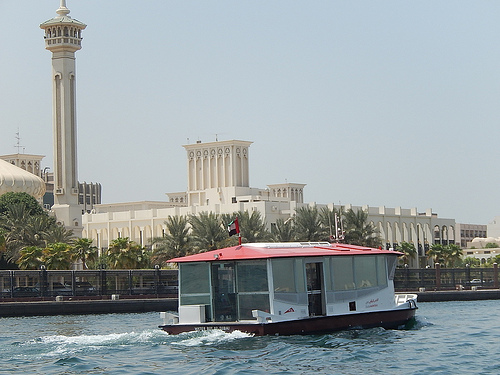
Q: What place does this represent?
A: It represents the city.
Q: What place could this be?
A: It is a city.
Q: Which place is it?
A: It is a city.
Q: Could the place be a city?
A: Yes, it is a city.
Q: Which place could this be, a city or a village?
A: It is a city.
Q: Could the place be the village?
A: No, it is the city.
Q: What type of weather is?
A: It is clear.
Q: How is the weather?
A: It is clear.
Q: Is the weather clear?
A: Yes, it is clear.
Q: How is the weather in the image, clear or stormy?
A: It is clear.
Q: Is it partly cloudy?
A: No, it is clear.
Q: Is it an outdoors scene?
A: Yes, it is outdoors.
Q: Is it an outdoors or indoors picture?
A: It is outdoors.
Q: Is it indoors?
A: No, it is outdoors.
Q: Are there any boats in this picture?
A: Yes, there is a boat.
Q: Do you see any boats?
A: Yes, there is a boat.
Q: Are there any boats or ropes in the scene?
A: Yes, there is a boat.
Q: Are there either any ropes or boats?
A: Yes, there is a boat.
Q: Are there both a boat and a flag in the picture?
A: Yes, there are both a boat and a flag.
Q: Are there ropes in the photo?
A: No, there are no ropes.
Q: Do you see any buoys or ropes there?
A: No, there are no ropes or buoys.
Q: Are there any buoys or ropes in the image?
A: No, there are no ropes or buoys.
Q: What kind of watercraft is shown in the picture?
A: The watercraft is a boat.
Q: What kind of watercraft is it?
A: The watercraft is a boat.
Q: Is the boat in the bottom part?
A: Yes, the boat is in the bottom of the image.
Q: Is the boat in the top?
A: No, the boat is in the bottom of the image.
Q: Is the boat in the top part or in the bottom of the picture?
A: The boat is in the bottom of the image.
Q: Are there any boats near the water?
A: Yes, there is a boat near the water.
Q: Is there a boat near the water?
A: Yes, there is a boat near the water.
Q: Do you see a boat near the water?
A: Yes, there is a boat near the water.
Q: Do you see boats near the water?
A: Yes, there is a boat near the water.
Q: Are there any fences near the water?
A: No, there is a boat near the water.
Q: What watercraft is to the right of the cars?
A: The watercraft is a boat.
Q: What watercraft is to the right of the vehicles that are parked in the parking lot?
A: The watercraft is a boat.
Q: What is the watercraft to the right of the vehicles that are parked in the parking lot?
A: The watercraft is a boat.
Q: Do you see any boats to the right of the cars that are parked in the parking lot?
A: Yes, there is a boat to the right of the cars.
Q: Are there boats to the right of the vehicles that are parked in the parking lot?
A: Yes, there is a boat to the right of the cars.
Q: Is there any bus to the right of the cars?
A: No, there is a boat to the right of the cars.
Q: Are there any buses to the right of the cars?
A: No, there is a boat to the right of the cars.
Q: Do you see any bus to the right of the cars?
A: No, there is a boat to the right of the cars.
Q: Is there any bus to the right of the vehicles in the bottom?
A: No, there is a boat to the right of the cars.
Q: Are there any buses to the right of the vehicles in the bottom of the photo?
A: No, there is a boat to the right of the cars.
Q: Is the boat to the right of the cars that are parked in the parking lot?
A: Yes, the boat is to the right of the cars.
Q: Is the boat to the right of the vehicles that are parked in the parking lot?
A: Yes, the boat is to the right of the cars.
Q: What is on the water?
A: The boat is on the water.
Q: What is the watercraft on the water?
A: The watercraft is a boat.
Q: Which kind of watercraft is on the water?
A: The watercraft is a boat.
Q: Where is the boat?
A: The boat is on the water.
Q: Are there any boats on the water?
A: Yes, there is a boat on the water.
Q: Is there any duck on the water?
A: No, there is a boat on the water.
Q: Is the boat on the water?
A: Yes, the boat is on the water.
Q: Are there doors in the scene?
A: Yes, there is a door.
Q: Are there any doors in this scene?
A: Yes, there is a door.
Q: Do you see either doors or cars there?
A: Yes, there is a door.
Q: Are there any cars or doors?
A: Yes, there is a door.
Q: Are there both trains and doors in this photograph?
A: No, there is a door but no trains.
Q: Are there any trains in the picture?
A: No, there are no trains.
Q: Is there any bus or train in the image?
A: No, there are no trains or buses.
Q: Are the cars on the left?
A: Yes, the cars are on the left of the image.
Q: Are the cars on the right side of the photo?
A: No, the cars are on the left of the image.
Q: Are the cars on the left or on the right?
A: The cars are on the left of the image.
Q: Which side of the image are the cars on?
A: The cars are on the left of the image.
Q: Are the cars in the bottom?
A: Yes, the cars are in the bottom of the image.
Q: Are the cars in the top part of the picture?
A: No, the cars are in the bottom of the image.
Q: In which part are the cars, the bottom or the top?
A: The cars are in the bottom of the image.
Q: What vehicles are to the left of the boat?
A: The vehicles are cars.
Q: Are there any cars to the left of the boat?
A: Yes, there are cars to the left of the boat.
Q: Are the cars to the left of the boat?
A: Yes, the cars are to the left of the boat.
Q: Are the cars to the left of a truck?
A: No, the cars are to the left of the boat.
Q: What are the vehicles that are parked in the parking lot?
A: The vehicles are cars.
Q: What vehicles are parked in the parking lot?
A: The vehicles are cars.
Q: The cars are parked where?
A: The cars are parked in the parking lot.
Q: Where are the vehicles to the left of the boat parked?
A: The cars are parked in the parking lot.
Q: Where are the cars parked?
A: The cars are parked in the parking lot.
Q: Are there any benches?
A: No, there are no benches.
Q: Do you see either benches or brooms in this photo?
A: No, there are no benches or brooms.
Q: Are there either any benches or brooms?
A: No, there are no benches or brooms.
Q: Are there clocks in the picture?
A: No, there are no clocks.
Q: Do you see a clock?
A: No, there are no clocks.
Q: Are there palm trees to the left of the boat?
A: Yes, there are palm trees to the left of the boat.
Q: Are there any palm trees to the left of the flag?
A: Yes, there are palm trees to the left of the flag.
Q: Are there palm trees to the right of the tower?
A: Yes, there are palm trees to the right of the tower.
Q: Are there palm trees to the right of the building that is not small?
A: Yes, there are palm trees to the right of the tower.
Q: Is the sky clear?
A: Yes, the sky is clear.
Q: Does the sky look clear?
A: Yes, the sky is clear.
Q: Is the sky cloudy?
A: No, the sky is clear.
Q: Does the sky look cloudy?
A: No, the sky is clear.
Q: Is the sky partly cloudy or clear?
A: The sky is clear.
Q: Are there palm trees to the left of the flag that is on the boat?
A: Yes, there are palm trees to the left of the flag.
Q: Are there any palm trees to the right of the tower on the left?
A: Yes, there are palm trees to the right of the tower.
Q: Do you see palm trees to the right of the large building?
A: Yes, there are palm trees to the right of the tower.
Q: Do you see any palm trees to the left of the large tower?
A: Yes, there is a palm tree to the left of the tower.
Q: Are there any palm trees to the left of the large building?
A: Yes, there is a palm tree to the left of the tower.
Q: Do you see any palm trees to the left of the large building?
A: Yes, there is a palm tree to the left of the tower.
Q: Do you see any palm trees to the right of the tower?
A: No, the palm tree is to the left of the tower.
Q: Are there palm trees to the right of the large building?
A: No, the palm tree is to the left of the tower.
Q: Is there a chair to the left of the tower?
A: No, there is a palm tree to the left of the tower.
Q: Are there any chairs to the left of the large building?
A: No, there is a palm tree to the left of the tower.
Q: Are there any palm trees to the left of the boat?
A: Yes, there is a palm tree to the left of the boat.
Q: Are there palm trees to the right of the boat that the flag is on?
A: No, the palm tree is to the left of the boat.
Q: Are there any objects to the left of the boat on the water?
A: No, there is a palm tree to the left of the boat.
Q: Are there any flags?
A: Yes, there is a flag.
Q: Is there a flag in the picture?
A: Yes, there is a flag.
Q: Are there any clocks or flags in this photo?
A: Yes, there is a flag.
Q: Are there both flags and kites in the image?
A: No, there is a flag but no kites.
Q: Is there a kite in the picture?
A: No, there are no kites.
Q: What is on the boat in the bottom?
A: The flag is on the boat.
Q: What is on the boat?
A: The flag is on the boat.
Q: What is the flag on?
A: The flag is on the boat.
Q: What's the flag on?
A: The flag is on the boat.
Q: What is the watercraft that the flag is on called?
A: The watercraft is a boat.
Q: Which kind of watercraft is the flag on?
A: The flag is on the boat.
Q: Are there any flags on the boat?
A: Yes, there is a flag on the boat.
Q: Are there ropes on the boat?
A: No, there is a flag on the boat.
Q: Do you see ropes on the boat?
A: No, there is a flag on the boat.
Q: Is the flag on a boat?
A: Yes, the flag is on a boat.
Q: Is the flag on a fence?
A: No, the flag is on a boat.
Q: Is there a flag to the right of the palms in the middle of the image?
A: Yes, there is a flag to the right of the palm trees.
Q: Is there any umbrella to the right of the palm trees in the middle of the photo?
A: No, there is a flag to the right of the palms.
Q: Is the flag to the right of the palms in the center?
A: Yes, the flag is to the right of the palms.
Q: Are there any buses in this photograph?
A: No, there are no buses.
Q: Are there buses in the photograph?
A: No, there are no buses.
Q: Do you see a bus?
A: No, there are no buses.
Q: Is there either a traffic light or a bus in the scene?
A: No, there are no buses or traffic lights.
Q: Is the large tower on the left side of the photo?
A: Yes, the tower is on the left of the image.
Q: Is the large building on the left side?
A: Yes, the tower is on the left of the image.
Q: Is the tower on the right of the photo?
A: No, the tower is on the left of the image.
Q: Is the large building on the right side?
A: No, the tower is on the left of the image.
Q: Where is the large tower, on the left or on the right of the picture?
A: The tower is on the left of the image.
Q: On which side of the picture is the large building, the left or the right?
A: The tower is on the left of the image.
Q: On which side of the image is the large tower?
A: The tower is on the left of the image.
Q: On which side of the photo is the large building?
A: The tower is on the left of the image.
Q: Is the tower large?
A: Yes, the tower is large.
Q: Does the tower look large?
A: Yes, the tower is large.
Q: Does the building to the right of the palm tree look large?
A: Yes, the tower is large.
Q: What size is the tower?
A: The tower is large.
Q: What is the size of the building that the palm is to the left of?
A: The tower is large.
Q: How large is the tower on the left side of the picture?
A: The tower is large.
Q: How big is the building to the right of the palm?
A: The tower is large.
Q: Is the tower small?
A: No, the tower is large.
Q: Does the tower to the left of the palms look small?
A: No, the tower is large.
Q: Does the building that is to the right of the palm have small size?
A: No, the tower is large.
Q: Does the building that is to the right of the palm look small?
A: No, the tower is large.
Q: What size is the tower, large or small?
A: The tower is large.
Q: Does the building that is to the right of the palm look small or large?
A: The tower is large.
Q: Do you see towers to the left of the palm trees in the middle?
A: Yes, there is a tower to the left of the palms.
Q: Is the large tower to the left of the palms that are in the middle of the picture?
A: Yes, the tower is to the left of the palms.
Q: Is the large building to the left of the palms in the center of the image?
A: Yes, the tower is to the left of the palms.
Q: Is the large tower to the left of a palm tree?
A: No, the tower is to the right of a palm tree.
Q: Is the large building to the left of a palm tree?
A: No, the tower is to the right of a palm tree.